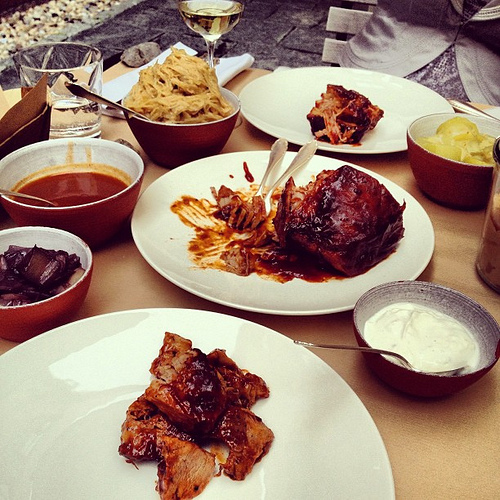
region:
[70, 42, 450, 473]
bowls and plates of food on table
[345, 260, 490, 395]
ceramic bowl with creamy sauce and a spoon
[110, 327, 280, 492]
cuts of meat with glazed sauce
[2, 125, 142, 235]
red bowl with hot sauce and utensil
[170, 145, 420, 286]
sauce smeared on a plate with chunk of cooked meat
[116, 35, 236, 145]
high mound of puree in dark bowl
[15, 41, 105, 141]
water in glass with cut designs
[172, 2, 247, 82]
white wine in stemmed glass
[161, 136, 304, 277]
sauce-covered utensils on white plate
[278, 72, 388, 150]
piece of meat pulling away from edge of bones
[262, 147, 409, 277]
the meat is cooked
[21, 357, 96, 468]
the plate is white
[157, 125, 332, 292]
the plate is messy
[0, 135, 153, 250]
the sauce is red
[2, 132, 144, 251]
the bowl is red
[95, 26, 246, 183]
the food is high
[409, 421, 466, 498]
the table is brown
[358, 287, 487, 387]
the sauce is white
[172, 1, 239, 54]
the wine is gold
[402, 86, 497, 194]
the pickles are green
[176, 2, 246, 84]
a glass of white wine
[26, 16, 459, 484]
dishes of food on a table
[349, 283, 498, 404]
white sauce in a bowl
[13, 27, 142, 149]
a glass of water on a table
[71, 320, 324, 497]
barbecue pork on a white plate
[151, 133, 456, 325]
a white plate with meat on it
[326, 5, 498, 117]
a person is sitting at the table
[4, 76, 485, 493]
the tablecloth is tan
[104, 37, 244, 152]
sweet potatoes in a bowl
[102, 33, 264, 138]
a white napkin on a table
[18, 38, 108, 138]
Glass cup next to the napkin holder.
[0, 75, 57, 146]
Napkin holder with the brown napkin in it.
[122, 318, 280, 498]
Meat with sauce on the big white plate.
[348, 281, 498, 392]
Gray bowl with white cream in it.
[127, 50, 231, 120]
Light brown cream behind plate that the fork is on.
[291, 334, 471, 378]
Spoon inside of the gray bowl with the white cream.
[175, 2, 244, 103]
Cup of wine behind the food.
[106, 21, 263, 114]
White napkin next to the glass of wine.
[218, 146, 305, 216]
Fork on the plate with the meat covered in sauce.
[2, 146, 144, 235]
Red bowl with red sauce in it.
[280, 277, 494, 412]
spoon in a white sauce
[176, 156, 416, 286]
meat dish on a white plate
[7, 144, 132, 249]
red sauce in a bowl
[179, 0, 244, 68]
wine glass filled with a light wine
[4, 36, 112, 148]
glass filled with water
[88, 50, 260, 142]
white napkin with utensils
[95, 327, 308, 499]
pork dish with a sauce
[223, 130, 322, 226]
two metal spoons for meat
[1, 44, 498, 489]
table with various bowls and plates